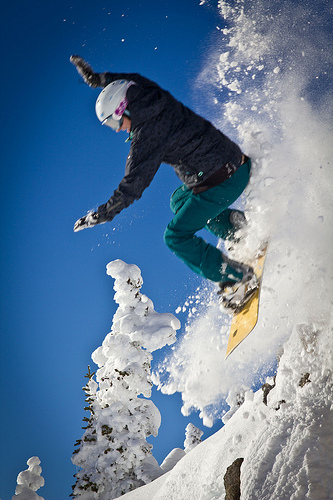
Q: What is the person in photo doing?
A: Snowboarding.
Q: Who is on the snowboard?
A: The person in the white helmet.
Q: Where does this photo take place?
A: At a ski mountain.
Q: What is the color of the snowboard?
A: Yellow.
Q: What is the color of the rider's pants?
A: Turquoise.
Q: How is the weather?
A: Sunny.